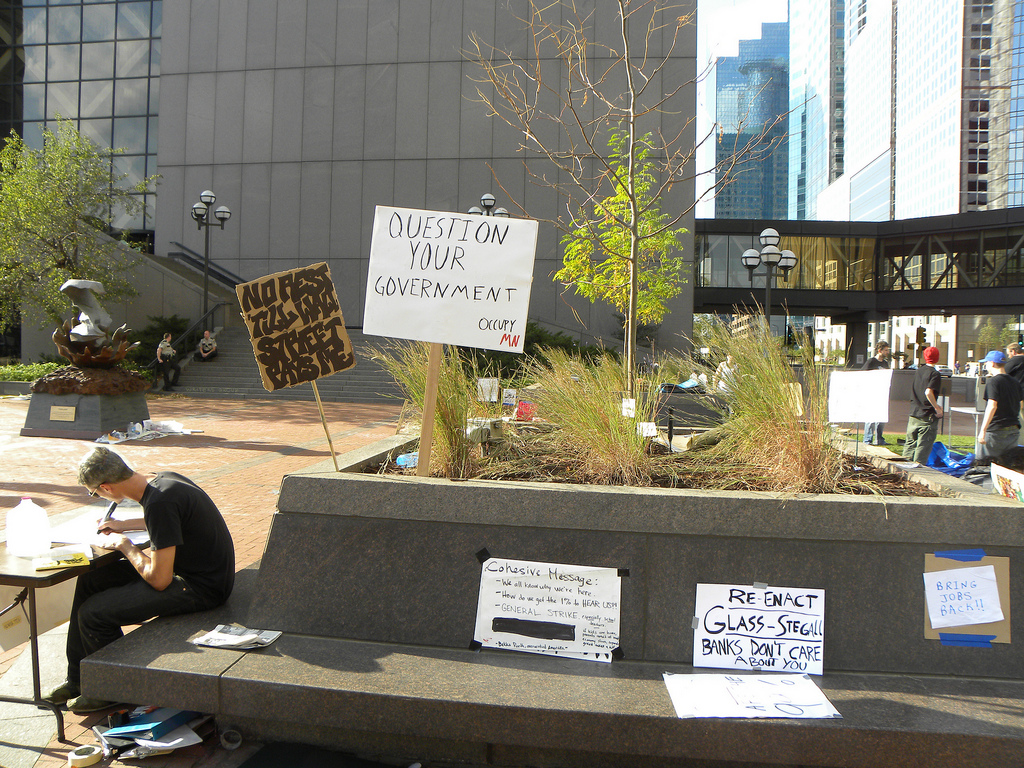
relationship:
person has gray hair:
[39, 437, 240, 718] [78, 444, 131, 486]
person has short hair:
[39, 437, 240, 718] [78, 444, 131, 486]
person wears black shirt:
[39, 437, 240, 718] [144, 469, 245, 602]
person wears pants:
[39, 437, 240, 718] [41, 548, 211, 726]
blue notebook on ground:
[100, 705, 195, 744] [0, 405, 366, 754]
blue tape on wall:
[929, 540, 995, 564] [279, 505, 1018, 686]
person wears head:
[39, 437, 240, 718] [923, 346, 940, 364]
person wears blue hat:
[974, 344, 1018, 455] [983, 348, 1011, 362]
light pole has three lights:
[182, 175, 236, 348] [186, 174, 234, 236]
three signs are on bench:
[463, 533, 1015, 685] [78, 494, 1019, 767]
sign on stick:
[342, 193, 556, 359] [407, 335, 449, 475]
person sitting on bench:
[39, 437, 240, 718] [78, 494, 1019, 767]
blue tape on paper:
[929, 540, 995, 564] [919, 566, 1007, 628]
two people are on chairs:
[898, 330, 1016, 487] [918, 443, 985, 478]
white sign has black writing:
[690, 573, 833, 677] [701, 599, 810, 655]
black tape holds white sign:
[470, 542, 639, 578] [462, 546, 640, 665]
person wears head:
[897, 337, 948, 461] [923, 346, 940, 364]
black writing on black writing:
[250, 285, 330, 385] [236, 261, 356, 392]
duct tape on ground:
[69, 739, 106, 763] [0, 405, 366, 754]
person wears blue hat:
[39, 437, 240, 718] [983, 348, 1011, 362]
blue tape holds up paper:
[929, 540, 995, 564] [919, 566, 1007, 628]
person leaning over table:
[39, 437, 240, 718] [4, 501, 158, 742]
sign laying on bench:
[656, 663, 849, 728] [78, 494, 1019, 767]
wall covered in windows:
[160, 10, 690, 299] [187, 33, 450, 203]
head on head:
[923, 346, 940, 364] [915, 341, 951, 379]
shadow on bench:
[126, 592, 379, 668] [78, 494, 1019, 767]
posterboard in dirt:
[355, 199, 528, 471] [388, 455, 911, 491]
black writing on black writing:
[701, 599, 810, 655] [236, 261, 356, 392]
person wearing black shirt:
[39, 437, 240, 718] [144, 469, 245, 602]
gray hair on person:
[78, 444, 131, 486] [39, 437, 240, 718]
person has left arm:
[39, 437, 240, 718] [95, 490, 182, 580]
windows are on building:
[187, 33, 450, 203] [155, 6, 702, 357]